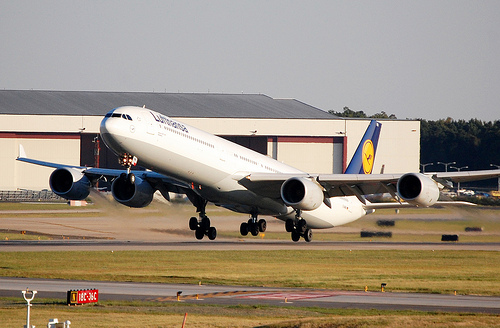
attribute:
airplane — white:
[130, 117, 236, 162]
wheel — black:
[201, 220, 209, 228]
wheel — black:
[190, 215, 196, 225]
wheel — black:
[210, 233, 215, 237]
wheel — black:
[197, 235, 202, 240]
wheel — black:
[285, 220, 291, 228]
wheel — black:
[307, 233, 312, 238]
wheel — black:
[292, 237, 296, 242]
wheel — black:
[252, 230, 257, 234]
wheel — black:
[241, 224, 246, 234]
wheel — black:
[249, 219, 252, 224]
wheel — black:
[262, 221, 265, 223]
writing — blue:
[152, 111, 177, 127]